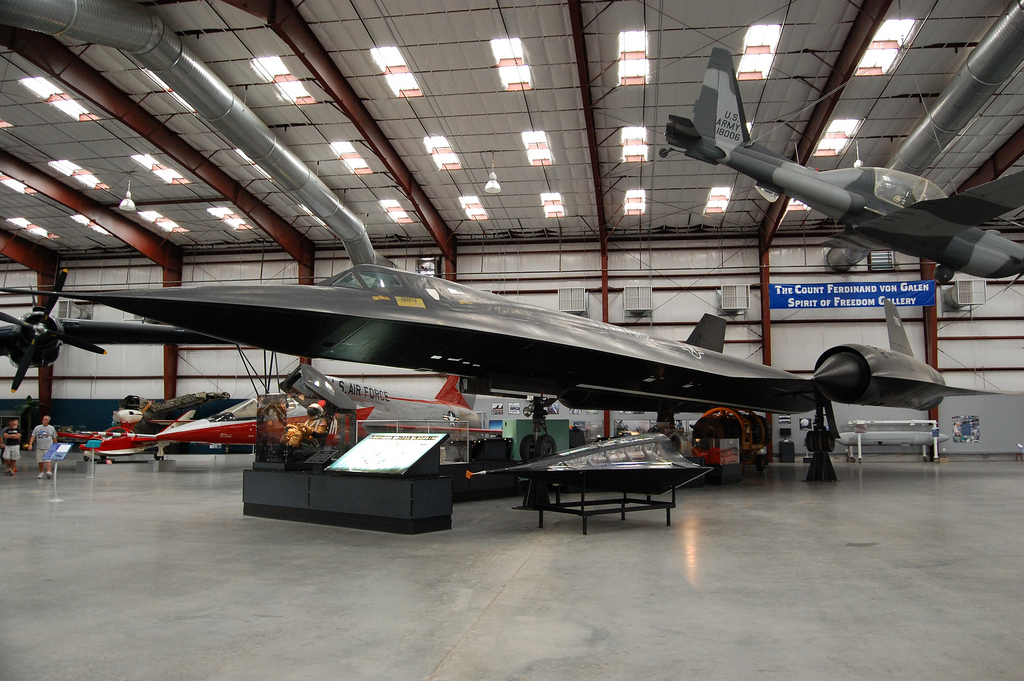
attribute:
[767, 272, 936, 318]
sign — white, blue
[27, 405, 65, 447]
tee shirt — grey tee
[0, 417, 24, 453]
shirt — black 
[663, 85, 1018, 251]
plane — grey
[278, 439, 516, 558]
counter — grey, black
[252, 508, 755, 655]
floor — orange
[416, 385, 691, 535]
aircraft — small, black 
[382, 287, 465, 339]
sticker — yellow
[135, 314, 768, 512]
plane — black 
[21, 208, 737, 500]
hangar — black 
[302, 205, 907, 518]
plane — black 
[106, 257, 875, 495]
airplane — black 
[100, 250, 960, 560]
aircraft — black 